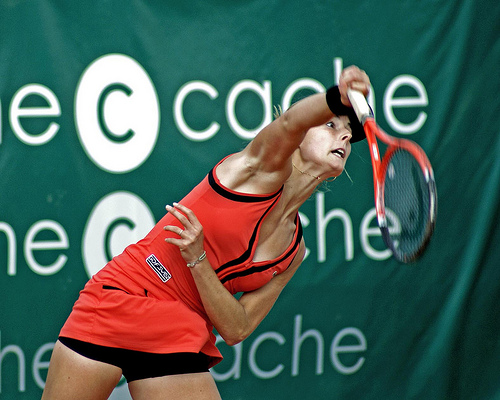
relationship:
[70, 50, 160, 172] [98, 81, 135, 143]
circle containing letter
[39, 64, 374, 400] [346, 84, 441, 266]
player holding racket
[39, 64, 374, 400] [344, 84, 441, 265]
player swinging racket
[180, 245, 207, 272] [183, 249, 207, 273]
bracelet on wrist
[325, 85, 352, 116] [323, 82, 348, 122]
band on wrist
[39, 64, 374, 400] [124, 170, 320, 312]
player wearing shirt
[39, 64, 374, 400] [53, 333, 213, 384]
player wearing shorts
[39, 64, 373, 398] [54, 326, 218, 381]
player wearing shorts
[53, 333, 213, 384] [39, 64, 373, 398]
shorts on player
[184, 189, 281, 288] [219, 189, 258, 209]
shirt with trim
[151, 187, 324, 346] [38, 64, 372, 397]
left hand of tennis player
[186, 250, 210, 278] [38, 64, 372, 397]
wrist of tennis player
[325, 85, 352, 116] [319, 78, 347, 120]
band on wrist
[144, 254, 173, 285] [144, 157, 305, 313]
logo of clothing brand on orange shirt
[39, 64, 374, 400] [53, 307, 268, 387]
player wearing shorts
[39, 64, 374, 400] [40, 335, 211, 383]
player wearing shorts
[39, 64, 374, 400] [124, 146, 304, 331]
player wearing a shirt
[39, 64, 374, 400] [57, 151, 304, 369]
player wearing a shirt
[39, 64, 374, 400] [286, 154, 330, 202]
player wearing a necklace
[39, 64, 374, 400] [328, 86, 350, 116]
player wearing a band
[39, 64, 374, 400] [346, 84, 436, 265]
player holding tennis racket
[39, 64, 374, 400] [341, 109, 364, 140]
player wearing a hat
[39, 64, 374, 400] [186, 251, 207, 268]
player wearing a bracelet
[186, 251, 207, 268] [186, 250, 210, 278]
bracelet on wrist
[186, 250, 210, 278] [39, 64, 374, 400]
wrist of player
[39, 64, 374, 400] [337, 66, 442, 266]
player swinging a racket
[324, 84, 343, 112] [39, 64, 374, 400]
wrist of player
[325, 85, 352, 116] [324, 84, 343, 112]
band on wrist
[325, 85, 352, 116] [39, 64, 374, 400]
band on player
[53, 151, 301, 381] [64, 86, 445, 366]
outfit on woman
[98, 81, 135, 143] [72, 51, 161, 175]
letter in circle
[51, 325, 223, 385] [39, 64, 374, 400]
shorts on player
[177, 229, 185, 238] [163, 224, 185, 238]
ring on ring finger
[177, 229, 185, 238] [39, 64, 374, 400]
ring on player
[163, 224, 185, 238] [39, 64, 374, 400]
ring finger of player